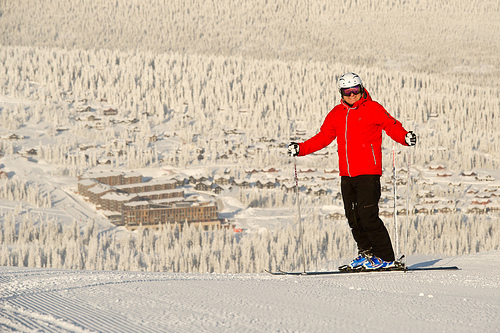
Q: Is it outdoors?
A: Yes, it is outdoors.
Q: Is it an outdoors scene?
A: Yes, it is outdoors.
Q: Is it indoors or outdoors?
A: It is outdoors.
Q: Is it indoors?
A: No, it is outdoors.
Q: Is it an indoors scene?
A: No, it is outdoors.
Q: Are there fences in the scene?
A: No, there are no fences.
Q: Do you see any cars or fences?
A: No, there are no fences or cars.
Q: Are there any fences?
A: No, there are no fences.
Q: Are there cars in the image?
A: No, there are no cars.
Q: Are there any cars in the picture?
A: No, there are no cars.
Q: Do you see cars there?
A: No, there are no cars.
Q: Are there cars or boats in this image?
A: No, there are no cars or boats.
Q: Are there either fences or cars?
A: No, there are no cars or fences.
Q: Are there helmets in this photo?
A: Yes, there is a helmet.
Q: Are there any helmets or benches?
A: Yes, there is a helmet.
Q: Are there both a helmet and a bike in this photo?
A: No, there is a helmet but no bikes.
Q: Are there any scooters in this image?
A: No, there are no scooters.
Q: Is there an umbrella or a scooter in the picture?
A: No, there are no scooters or umbrellas.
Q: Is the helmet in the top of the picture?
A: Yes, the helmet is in the top of the image.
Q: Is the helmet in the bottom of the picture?
A: No, the helmet is in the top of the image.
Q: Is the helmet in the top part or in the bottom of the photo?
A: The helmet is in the top of the image.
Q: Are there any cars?
A: No, there are no cars.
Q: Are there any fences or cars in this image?
A: No, there are no cars or fences.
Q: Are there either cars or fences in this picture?
A: No, there are no cars or fences.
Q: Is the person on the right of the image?
A: Yes, the person is on the right of the image.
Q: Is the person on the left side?
A: No, the person is on the right of the image.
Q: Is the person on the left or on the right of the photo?
A: The person is on the right of the image.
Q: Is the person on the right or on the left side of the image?
A: The person is on the right of the image.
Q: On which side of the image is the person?
A: The person is on the right of the image.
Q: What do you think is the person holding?
A: The person is holding the pole.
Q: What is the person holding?
A: The person is holding the pole.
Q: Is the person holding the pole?
A: Yes, the person is holding the pole.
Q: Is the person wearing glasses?
A: Yes, the person is wearing glasses.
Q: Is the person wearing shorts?
A: No, the person is wearing glasses.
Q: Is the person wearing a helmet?
A: Yes, the person is wearing a helmet.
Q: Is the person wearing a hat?
A: No, the person is wearing a helmet.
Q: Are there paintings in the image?
A: No, there are no paintings.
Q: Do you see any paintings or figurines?
A: No, there are no paintings or figurines.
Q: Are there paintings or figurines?
A: No, there are no paintings or figurines.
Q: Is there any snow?
A: Yes, there is snow.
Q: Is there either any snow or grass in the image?
A: Yes, there is snow.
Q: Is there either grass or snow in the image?
A: Yes, there is snow.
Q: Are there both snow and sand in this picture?
A: No, there is snow but no sand.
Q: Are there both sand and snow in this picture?
A: No, there is snow but no sand.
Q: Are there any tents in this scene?
A: No, there are no tents.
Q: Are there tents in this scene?
A: No, there are no tents.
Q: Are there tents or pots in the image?
A: No, there are no tents or pots.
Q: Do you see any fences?
A: No, there are no fences.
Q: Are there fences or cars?
A: No, there are no fences or cars.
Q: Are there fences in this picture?
A: No, there are no fences.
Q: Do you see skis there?
A: Yes, there are skis.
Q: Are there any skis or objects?
A: Yes, there are skis.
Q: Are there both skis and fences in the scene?
A: No, there are skis but no fences.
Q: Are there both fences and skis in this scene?
A: No, there are skis but no fences.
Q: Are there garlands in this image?
A: No, there are no garlands.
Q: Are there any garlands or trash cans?
A: No, there are no garlands or trash cans.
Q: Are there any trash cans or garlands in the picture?
A: No, there are no garlands or trash cans.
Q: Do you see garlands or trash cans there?
A: No, there are no garlands or trash cans.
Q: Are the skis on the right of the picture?
A: Yes, the skis are on the right of the image.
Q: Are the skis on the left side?
A: No, the skis are on the right of the image.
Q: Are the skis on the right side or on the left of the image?
A: The skis are on the right of the image.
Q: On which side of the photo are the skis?
A: The skis are on the right of the image.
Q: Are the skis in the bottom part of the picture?
A: Yes, the skis are in the bottom of the image.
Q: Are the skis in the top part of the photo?
A: No, the skis are in the bottom of the image.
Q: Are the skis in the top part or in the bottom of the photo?
A: The skis are in the bottom of the image.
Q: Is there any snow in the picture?
A: Yes, there is snow.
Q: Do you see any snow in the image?
A: Yes, there is snow.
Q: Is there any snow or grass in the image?
A: Yes, there is snow.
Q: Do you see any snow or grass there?
A: Yes, there is snow.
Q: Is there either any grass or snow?
A: Yes, there is snow.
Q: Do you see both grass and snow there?
A: No, there is snow but no grass.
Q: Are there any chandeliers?
A: No, there are no chandeliers.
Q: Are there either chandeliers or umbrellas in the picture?
A: No, there are no chandeliers or umbrellas.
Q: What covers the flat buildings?
A: The snow covers the buildings.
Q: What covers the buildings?
A: The snow covers the buildings.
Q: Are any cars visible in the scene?
A: No, there are no cars.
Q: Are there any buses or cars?
A: No, there are no cars or buses.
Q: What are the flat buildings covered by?
A: The buildings are covered by the snow.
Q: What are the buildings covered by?
A: The buildings are covered by the snow.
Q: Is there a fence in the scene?
A: No, there are no fences.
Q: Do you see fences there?
A: No, there are no fences.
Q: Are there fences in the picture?
A: No, there are no fences.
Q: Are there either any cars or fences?
A: No, there are no fences or cars.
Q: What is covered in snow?
A: The trees are covered in snow.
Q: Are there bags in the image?
A: No, there are no bags.